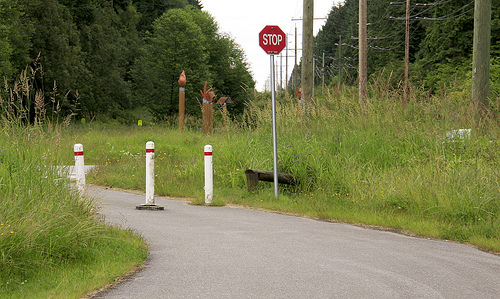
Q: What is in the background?
A: Green trees.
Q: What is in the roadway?
A: White blockades.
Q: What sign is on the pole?
A: Stop sign.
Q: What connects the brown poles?
A: Electrical wires.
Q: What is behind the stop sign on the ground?
A: Pipe rail.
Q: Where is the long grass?
A: On the left side.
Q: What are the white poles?
A: Barrier to the road.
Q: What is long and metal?
A: Pole.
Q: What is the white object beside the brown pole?
A: Sign.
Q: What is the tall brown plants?
A: Ferns.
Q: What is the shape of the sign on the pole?
A: Octogon.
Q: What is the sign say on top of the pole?
A: Stop.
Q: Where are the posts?
A: In the road.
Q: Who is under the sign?
A: No one.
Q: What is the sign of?
A: Stop sign.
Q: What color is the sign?
A: Red and white.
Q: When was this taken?
A: During the day.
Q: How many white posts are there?
A: Three.